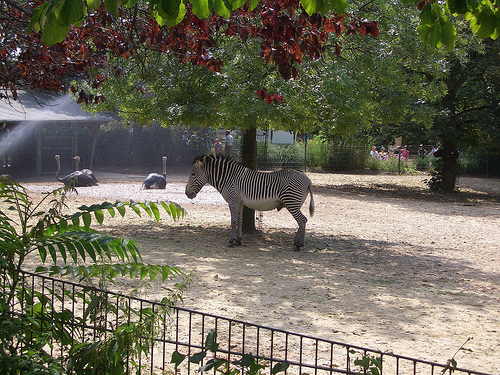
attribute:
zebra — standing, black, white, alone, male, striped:
[183, 152, 315, 251]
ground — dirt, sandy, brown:
[1, 173, 499, 372]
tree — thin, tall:
[240, 122, 260, 235]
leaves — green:
[74, 2, 408, 143]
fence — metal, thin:
[6, 264, 478, 374]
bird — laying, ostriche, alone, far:
[139, 155, 171, 191]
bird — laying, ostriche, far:
[52, 153, 91, 185]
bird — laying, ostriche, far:
[75, 153, 100, 181]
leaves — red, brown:
[3, 2, 381, 100]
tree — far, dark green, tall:
[420, 66, 468, 195]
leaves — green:
[3, 176, 184, 369]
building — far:
[0, 88, 116, 178]